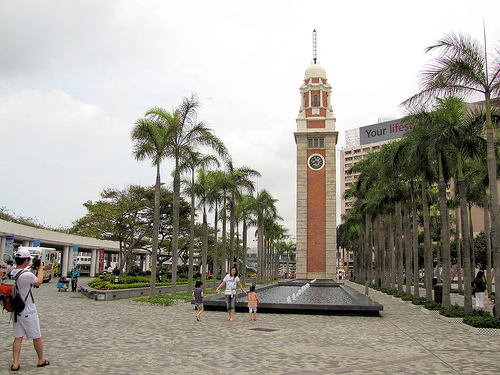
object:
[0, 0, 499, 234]
cloud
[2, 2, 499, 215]
sky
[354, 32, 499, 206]
leaves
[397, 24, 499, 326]
tree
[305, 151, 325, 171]
clock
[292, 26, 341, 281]
tower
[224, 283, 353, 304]
water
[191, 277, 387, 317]
pool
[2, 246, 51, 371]
man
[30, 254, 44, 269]
camera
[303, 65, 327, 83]
dome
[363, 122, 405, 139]
words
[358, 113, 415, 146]
sign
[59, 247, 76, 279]
columns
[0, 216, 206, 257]
structure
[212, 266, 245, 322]
woman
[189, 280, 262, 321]
children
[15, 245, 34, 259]
hat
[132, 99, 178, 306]
palm tree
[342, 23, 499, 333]
row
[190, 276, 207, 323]
child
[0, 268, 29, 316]
backpack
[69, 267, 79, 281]
shirt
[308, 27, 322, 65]
point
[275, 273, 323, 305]
fountain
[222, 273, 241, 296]
shirt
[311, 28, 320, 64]
antennae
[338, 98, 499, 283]
building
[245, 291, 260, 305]
shirt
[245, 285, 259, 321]
girl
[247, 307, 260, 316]
shorts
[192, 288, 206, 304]
shirt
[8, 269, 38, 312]
shirt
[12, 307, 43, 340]
shorts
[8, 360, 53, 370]
sandals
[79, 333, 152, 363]
pattern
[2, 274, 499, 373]
ground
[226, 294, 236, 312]
capris